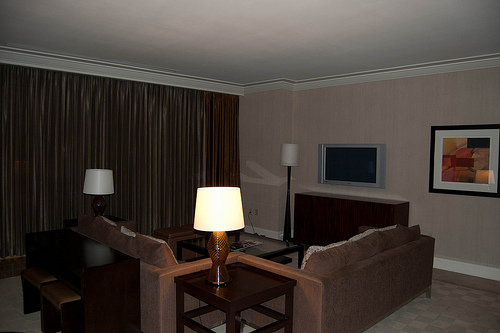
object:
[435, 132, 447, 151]
picture part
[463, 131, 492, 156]
picture part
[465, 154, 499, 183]
picture part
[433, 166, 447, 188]
picture part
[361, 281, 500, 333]
carpet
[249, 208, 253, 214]
outlet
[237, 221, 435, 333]
couch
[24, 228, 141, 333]
table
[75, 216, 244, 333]
couch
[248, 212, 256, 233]
cord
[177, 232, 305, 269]
table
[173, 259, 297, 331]
table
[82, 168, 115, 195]
lamp shade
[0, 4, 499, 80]
ceiling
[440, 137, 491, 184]
picture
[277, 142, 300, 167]
lamp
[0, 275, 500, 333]
ground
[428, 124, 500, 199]
frame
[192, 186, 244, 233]
lamp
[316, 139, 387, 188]
television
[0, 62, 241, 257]
blinds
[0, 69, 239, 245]
window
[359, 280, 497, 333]
floor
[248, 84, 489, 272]
wall